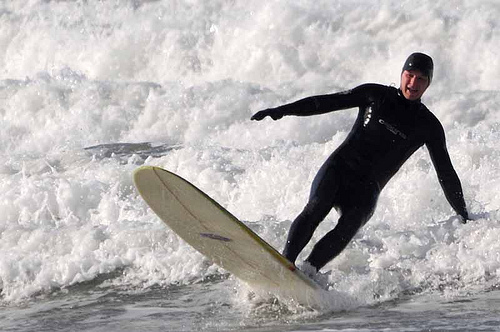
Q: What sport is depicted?
A: Surfing.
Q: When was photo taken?
A: Daytime.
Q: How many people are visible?
A: 1.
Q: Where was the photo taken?
A: Beach.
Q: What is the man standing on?
A: Surfboard.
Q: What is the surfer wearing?
A: Suit.